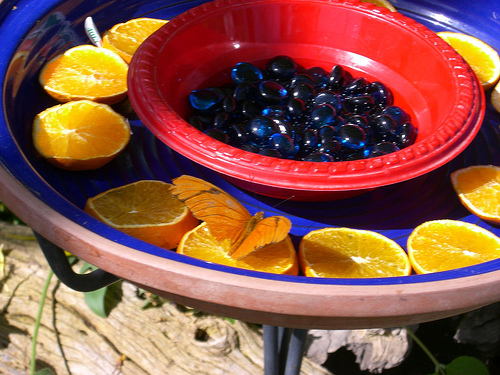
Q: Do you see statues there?
A: No, there are no statues.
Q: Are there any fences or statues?
A: No, there are no statues or fences.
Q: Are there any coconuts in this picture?
A: No, there are no coconuts.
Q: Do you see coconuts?
A: No, there are no coconuts.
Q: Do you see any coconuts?
A: No, there are no coconuts.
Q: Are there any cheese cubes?
A: No, there are no cheese cubes.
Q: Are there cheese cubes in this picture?
A: No, there are no cheese cubes.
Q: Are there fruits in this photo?
A: Yes, there is a fruit.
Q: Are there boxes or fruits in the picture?
A: Yes, there is a fruit.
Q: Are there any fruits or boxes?
A: Yes, there is a fruit.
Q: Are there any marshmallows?
A: No, there are no marshmallows.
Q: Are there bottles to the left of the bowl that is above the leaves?
A: No, there is a fruit to the left of the bowl.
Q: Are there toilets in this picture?
A: No, there are no toilets.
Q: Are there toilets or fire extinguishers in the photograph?
A: No, there are no toilets or fire extinguishers.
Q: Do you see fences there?
A: No, there are no fences.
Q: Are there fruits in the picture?
A: Yes, there is a fruit.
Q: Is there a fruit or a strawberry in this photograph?
A: Yes, there is a fruit.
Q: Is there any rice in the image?
A: No, there is no rice.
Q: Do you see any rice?
A: No, there is no rice.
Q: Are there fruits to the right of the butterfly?
A: Yes, there is a fruit to the right of the butterfly.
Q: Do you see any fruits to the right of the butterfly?
A: Yes, there is a fruit to the right of the butterfly.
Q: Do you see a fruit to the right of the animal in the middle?
A: Yes, there is a fruit to the right of the butterfly.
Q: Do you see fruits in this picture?
A: Yes, there is a fruit.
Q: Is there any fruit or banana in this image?
A: Yes, there is a fruit.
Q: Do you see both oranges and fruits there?
A: Yes, there are both a fruit and oranges.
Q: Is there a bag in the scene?
A: No, there are no bags.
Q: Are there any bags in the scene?
A: No, there are no bags.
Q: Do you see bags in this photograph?
A: No, there are no bags.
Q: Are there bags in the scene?
A: No, there are no bags.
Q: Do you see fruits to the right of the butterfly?
A: Yes, there is a fruit to the right of the butterfly.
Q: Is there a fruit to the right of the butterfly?
A: Yes, there is a fruit to the right of the butterfly.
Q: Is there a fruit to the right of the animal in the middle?
A: Yes, there is a fruit to the right of the butterfly.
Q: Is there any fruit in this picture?
A: Yes, there is a fruit.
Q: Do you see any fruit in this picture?
A: Yes, there is a fruit.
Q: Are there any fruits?
A: Yes, there is a fruit.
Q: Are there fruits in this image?
A: Yes, there is a fruit.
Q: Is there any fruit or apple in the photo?
A: Yes, there is a fruit.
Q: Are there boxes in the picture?
A: No, there are no boxes.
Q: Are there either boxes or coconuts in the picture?
A: No, there are no boxes or coconuts.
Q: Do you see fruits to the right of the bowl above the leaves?
A: No, the fruit is to the left of the bowl.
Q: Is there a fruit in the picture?
A: Yes, there is a fruit.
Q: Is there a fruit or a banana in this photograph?
A: Yes, there is a fruit.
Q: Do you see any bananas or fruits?
A: Yes, there is a fruit.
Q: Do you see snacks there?
A: No, there are no snacks.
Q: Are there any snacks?
A: No, there are no snacks.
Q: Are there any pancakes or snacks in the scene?
A: No, there are no snacks or pancakes.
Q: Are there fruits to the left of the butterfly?
A: Yes, there is a fruit to the left of the butterfly.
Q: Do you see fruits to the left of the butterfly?
A: Yes, there is a fruit to the left of the butterfly.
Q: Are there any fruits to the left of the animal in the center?
A: Yes, there is a fruit to the left of the butterfly.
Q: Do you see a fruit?
A: Yes, there is a fruit.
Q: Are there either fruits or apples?
A: Yes, there is a fruit.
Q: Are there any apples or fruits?
A: Yes, there is a fruit.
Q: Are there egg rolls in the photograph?
A: No, there are no egg rolls.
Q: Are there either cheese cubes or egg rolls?
A: No, there are no egg rolls or cheese cubes.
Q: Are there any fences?
A: No, there are no fences.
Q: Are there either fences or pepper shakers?
A: No, there are no fences or pepper shakers.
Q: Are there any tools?
A: No, there are no tools.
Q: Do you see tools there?
A: No, there are no tools.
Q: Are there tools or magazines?
A: No, there are no tools or magazines.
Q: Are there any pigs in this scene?
A: No, there are no pigs.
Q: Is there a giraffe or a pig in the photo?
A: No, there are no pigs or giraffes.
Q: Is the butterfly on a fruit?
A: Yes, the butterfly is on a fruit.